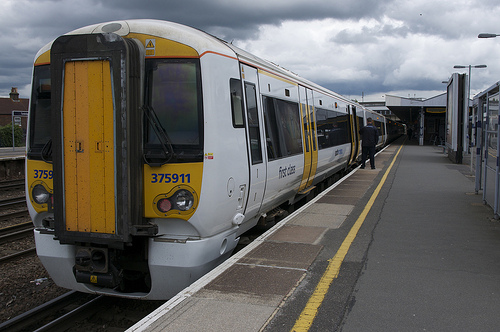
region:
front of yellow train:
[38, 58, 198, 253]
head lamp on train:
[155, 204, 202, 217]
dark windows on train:
[261, 103, 311, 153]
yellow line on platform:
[322, 243, 367, 273]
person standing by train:
[347, 113, 381, 167]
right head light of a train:
[17, 175, 59, 212]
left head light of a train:
[148, 175, 198, 227]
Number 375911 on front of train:
[145, 168, 198, 188]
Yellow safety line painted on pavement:
[328, 198, 377, 270]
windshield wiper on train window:
[133, 96, 187, 165]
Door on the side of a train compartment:
[234, 56, 275, 234]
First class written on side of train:
[270, 155, 304, 183]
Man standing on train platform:
[353, 113, 386, 183]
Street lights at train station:
[445, 54, 491, 184]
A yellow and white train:
[18, 15, 400, 311]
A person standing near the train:
[357, 113, 382, 170]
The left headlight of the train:
[164, 185, 196, 212]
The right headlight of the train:
[24, 180, 52, 209]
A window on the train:
[137, 50, 210, 169]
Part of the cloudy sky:
[338, 33, 403, 73]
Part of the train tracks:
[29, 304, 59, 326]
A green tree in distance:
[1, 118, 23, 148]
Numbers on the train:
[148, 168, 194, 186]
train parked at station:
[28, 18, 398, 301]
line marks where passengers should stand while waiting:
[293, 142, 406, 331]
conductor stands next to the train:
[357, 117, 376, 169]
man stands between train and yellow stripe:
[357, 115, 379, 170]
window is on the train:
[142, 54, 202, 163]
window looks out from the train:
[261, 93, 308, 159]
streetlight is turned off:
[453, 61, 488, 166]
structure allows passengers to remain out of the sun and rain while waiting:
[382, 89, 448, 144]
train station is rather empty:
[24, 17, 499, 330]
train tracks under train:
[0, 289, 167, 330]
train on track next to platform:
[21, 21, 468, 328]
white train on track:
[49, 12, 405, 328]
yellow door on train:
[39, 35, 178, 244]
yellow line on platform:
[273, 127, 413, 328]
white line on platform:
[133, 92, 383, 324]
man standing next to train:
[347, 106, 387, 165]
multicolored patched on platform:
[106, 172, 366, 328]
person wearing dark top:
[355, 123, 381, 148]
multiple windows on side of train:
[231, 73, 401, 172]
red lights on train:
[146, 178, 179, 233]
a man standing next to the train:
[357, 116, 378, 166]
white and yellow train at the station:
[23, 17, 406, 301]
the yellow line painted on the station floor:
[292, 142, 403, 330]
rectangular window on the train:
[261, 95, 303, 162]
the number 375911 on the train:
[149, 171, 192, 185]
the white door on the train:
[239, 61, 268, 223]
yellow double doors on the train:
[297, 83, 318, 193]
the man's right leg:
[366, 145, 373, 168]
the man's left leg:
[357, 143, 367, 168]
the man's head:
[363, 116, 373, 126]